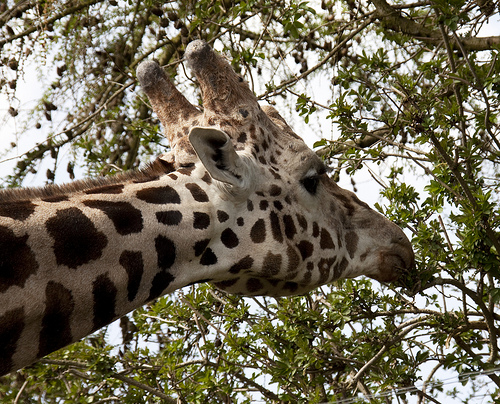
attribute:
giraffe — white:
[0, 39, 415, 377]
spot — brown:
[136, 185, 180, 203]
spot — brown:
[84, 199, 146, 236]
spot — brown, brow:
[45, 206, 110, 270]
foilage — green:
[374, 167, 458, 275]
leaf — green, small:
[304, 114, 309, 125]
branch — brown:
[282, 88, 335, 113]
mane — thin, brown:
[0, 157, 177, 203]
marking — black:
[315, 162, 328, 175]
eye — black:
[299, 174, 321, 196]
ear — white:
[187, 126, 251, 189]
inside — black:
[204, 136, 242, 180]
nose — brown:
[399, 236, 416, 269]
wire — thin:
[345, 368, 498, 403]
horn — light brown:
[186, 40, 258, 118]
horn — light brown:
[136, 60, 201, 142]